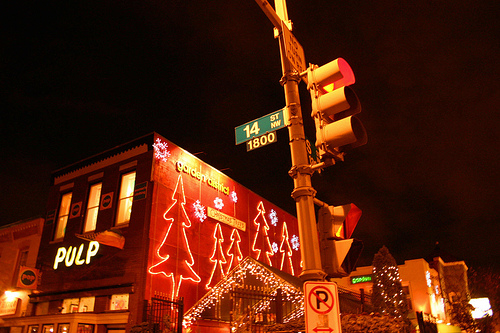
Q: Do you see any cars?
A: No, there are no cars.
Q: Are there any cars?
A: No, there are no cars.